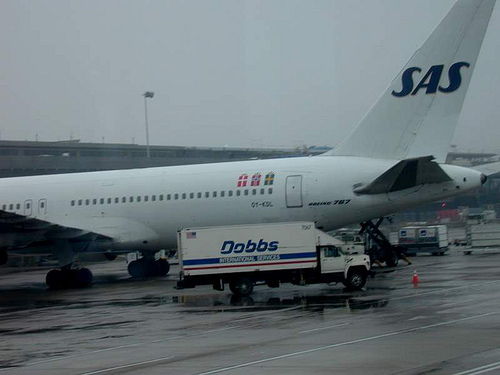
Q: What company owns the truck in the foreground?
A: Dobbs.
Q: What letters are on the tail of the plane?
A: SAS.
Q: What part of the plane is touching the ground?
A: Landing gear.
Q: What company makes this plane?
A: Boeing.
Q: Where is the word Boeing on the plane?
A: Beneath the tail.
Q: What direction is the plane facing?
A: The left.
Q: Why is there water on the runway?
A: It recently rained.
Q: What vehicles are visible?
A: Airplanes and trucks.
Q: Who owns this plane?
A: SAS.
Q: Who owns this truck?
A: Dobbs.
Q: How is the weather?
A: Rainy.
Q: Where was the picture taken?
A: Airport.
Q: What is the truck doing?
A: Loading the plane.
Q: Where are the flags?
A: Over the plane's windows.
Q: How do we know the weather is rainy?
A: There is water on the pavement.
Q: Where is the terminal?
A: Behind the plane.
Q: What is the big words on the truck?
A: Dobbs.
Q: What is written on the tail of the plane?
A: SAS.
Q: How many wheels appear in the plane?
A: 4.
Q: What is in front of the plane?
A: A truck.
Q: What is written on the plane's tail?
A: SAS.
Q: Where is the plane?
A: An airport.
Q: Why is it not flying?
A: Refueling.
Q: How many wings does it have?
A: Two.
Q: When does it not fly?
A: Bad weather.